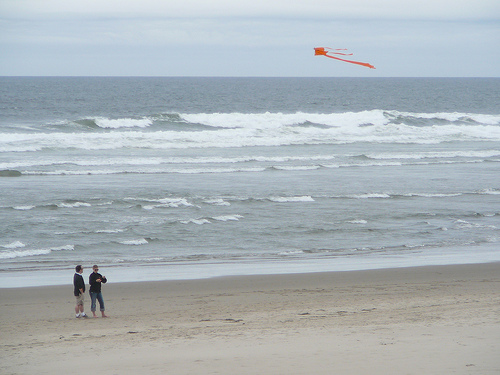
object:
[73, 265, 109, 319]
couple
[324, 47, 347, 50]
streamer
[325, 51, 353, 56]
streamer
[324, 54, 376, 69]
streamer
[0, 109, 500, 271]
wave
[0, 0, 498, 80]
sky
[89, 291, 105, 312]
capris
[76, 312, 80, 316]
socks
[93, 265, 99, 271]
hair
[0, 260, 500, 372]
sand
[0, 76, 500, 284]
water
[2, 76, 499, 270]
ocean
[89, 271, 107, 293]
sweater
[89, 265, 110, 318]
people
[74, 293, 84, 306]
shorts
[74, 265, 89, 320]
man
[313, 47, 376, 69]
kite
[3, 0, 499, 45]
cloud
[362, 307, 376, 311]
track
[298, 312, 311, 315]
track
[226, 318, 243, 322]
track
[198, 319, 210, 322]
track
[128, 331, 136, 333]
track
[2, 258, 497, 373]
beach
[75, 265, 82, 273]
hair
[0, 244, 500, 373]
shore